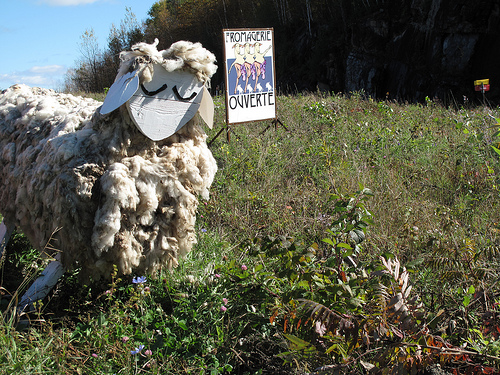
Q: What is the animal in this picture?
A: Sheep.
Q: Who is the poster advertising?
A: Fromagerie Ouverte.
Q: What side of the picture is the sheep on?
A: Left.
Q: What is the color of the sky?
A: Blue.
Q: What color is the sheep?
A: White.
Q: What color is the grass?
A: Green.